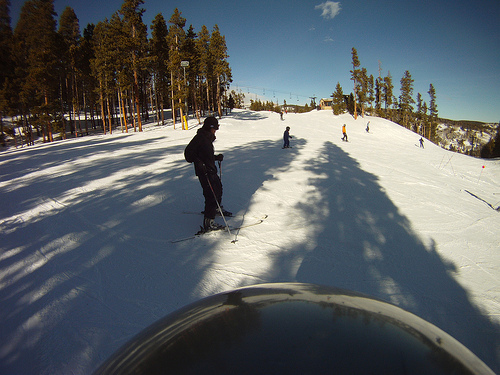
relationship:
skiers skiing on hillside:
[177, 108, 428, 233] [0, 105, 500, 375]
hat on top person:
[201, 115, 218, 125] [183, 115, 234, 235]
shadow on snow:
[0, 133, 500, 375] [0, 103, 499, 353]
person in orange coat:
[338, 122, 349, 140] [340, 127, 351, 133]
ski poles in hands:
[218, 159, 222, 181] [190, 152, 223, 163]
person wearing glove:
[183, 115, 234, 235] [216, 151, 225, 163]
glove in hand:
[216, 151, 225, 163] [213, 150, 227, 167]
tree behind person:
[0, 0, 56, 149] [183, 115, 234, 235]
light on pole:
[179, 59, 189, 66] [180, 66, 187, 116]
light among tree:
[179, 59, 189, 66] [0, 0, 56, 149]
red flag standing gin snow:
[474, 162, 491, 186] [0, 103, 499, 353]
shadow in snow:
[0, 133, 500, 375] [0, 103, 499, 353]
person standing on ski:
[183, 115, 234, 235] [182, 219, 243, 240]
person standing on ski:
[183, 115, 234, 235] [180, 201, 256, 221]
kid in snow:
[282, 127, 297, 152] [156, 116, 441, 271]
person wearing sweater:
[340, 123, 348, 141] [341, 124, 348, 137]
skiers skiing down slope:
[177, 108, 428, 233] [0, 105, 497, 372]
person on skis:
[183, 115, 234, 235] [181, 210, 268, 220]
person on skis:
[183, 115, 234, 235] [174, 222, 278, 237]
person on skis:
[183, 115, 234, 235] [171, 203, 273, 246]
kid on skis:
[282, 126, 293, 150] [281, 146, 290, 150]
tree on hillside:
[0, 0, 56, 149] [0, 101, 497, 373]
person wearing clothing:
[183, 115, 234, 235] [184, 115, 235, 233]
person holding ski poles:
[183, 115, 234, 235] [191, 155, 243, 228]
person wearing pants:
[186, 115, 231, 233] [195, 170, 225, 217]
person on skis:
[366, 116, 369, 137] [362, 130, 374, 135]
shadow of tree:
[236, 139, 498, 374] [10, 7, 243, 131]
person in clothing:
[183, 115, 234, 235] [174, 109, 257, 249]